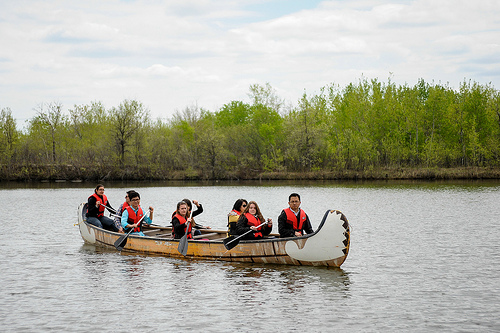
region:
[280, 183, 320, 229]
man in a boat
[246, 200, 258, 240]
woman in a boat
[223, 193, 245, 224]
woman in a boat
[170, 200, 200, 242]
woman in a boat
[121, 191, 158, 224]
woman in a boat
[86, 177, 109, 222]
woman in a boat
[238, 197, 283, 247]
woman holding an oar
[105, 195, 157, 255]
man holding an oar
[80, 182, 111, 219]
woman holding an oar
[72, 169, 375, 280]
people in a boat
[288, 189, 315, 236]
A person in a boat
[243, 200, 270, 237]
A person in a boat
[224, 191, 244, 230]
A person in a boat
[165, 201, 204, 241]
A person in a boat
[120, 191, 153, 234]
A person in a boat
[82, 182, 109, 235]
A person in a boat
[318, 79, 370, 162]
A short green tree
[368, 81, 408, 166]
A short green tree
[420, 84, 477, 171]
A short green tree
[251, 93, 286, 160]
A short green tree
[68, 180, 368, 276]
people in a canoe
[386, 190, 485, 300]
still water under a canoe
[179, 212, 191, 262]
oar in girl's hand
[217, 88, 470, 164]
trees on edge of water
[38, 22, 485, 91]
cloudy sky in the distance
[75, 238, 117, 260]
shadow in the water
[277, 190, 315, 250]
man in front of canoe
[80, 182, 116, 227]
woman on back of canoe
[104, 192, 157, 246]
boy paddling with an oar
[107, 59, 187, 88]
white cloud in the sky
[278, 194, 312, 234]
person riding in kayak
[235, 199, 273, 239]
person riding in kayak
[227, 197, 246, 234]
person riding in kayak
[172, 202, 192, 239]
person riding in kayak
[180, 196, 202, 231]
person riding in kayak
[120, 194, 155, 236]
person riding in kayak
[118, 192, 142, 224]
person riding in kayak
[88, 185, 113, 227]
person riding in kayak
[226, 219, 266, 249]
black colored kayak paddle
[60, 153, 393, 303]
People are in a canoe on a lake.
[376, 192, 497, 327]
The water is bluish green.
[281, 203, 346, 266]
A white object painted on the front of the canoe.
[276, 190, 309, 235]
The man is wearing a life jacket.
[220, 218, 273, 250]
The woman is holding an oar.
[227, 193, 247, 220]
Another woman is sitting next to a woman holding the oar.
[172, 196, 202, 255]
The woman had an oar in her hand.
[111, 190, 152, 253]
The man has an oar in his hand.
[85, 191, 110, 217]
The woman is wearing a life vest.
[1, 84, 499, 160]
Green trees are on the shore.